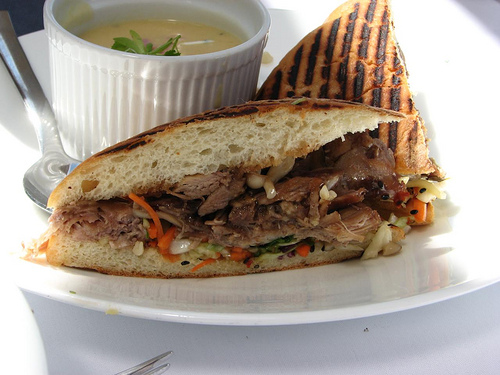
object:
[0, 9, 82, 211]
spoon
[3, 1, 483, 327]
plate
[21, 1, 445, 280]
sandwiches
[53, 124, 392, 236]
stuffing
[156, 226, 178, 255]
slice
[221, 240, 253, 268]
slice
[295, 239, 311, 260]
slice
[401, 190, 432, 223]
slice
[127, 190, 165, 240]
piece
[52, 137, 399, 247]
meat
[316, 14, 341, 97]
line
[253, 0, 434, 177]
bread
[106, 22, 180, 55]
leaf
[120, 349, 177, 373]
tines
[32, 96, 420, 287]
half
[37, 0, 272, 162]
bowl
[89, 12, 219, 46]
soup